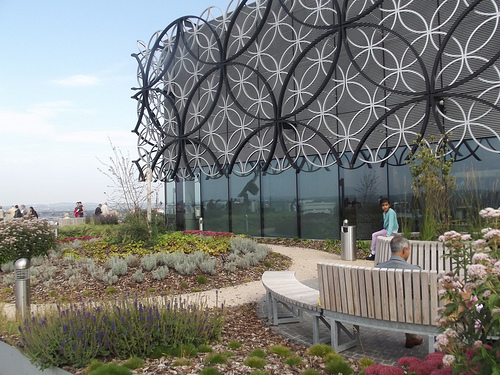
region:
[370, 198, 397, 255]
child sitting on top of the bench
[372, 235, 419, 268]
old man sitting at the bench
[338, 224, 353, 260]
silver trash can next to the bench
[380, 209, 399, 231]
blue shirt on the child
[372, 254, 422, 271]
gray shirt on the old man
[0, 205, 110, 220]
group of people walking on the sidewalk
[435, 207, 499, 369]
light pink flowers in the garden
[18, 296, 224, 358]
group of purple flowers in the garden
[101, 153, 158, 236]
small trees with no leaves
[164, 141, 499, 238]
large windows on the side of the building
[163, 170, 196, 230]
window of a building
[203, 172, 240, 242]
window of a building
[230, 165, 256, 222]
window of a building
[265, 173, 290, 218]
window of a building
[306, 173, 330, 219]
window of a building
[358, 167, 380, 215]
window of a building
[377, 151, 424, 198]
window of a building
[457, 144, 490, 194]
window of a building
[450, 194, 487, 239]
window of a building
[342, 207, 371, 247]
window of a building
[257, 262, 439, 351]
bench for seating and resting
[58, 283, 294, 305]
path in the green space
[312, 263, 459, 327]
seat with back area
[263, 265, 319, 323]
seat with no back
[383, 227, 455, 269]
seat in the green space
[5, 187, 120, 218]
people near the green space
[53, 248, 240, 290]
plants in the garden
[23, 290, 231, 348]
plants in the garden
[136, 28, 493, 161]
design on the building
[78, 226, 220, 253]
plants in the garden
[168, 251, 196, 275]
this is a flower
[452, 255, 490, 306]
this is a flower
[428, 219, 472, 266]
this is a flower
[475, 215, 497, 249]
this is a flower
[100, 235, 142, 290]
this is a flower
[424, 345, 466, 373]
this is a flower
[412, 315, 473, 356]
this is a flower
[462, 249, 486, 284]
this is a flower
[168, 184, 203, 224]
window of a building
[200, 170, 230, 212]
window of a building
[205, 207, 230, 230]
window of a building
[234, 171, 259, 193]
window of a building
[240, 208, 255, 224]
window of a building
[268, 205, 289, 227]
window of a building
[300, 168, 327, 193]
window of a building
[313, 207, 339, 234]
window of a building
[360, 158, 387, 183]
window of a building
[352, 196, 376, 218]
window of a building